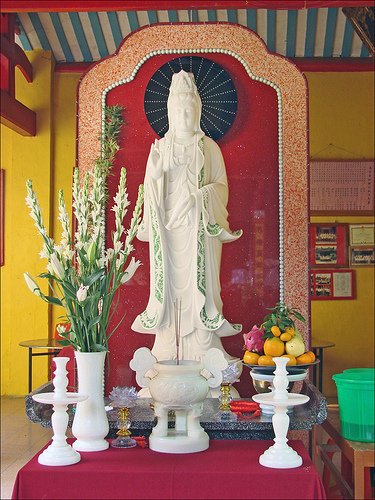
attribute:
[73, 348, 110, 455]
vase — white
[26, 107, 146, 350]
flowers — white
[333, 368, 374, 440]
tub — green, plastic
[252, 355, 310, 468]
candle holder — white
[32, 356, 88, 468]
candle holder — white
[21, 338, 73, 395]
table — glass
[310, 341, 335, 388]
table — glass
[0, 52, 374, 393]
wall — yellow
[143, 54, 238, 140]
medaillon — white, round, black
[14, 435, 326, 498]
cloth — red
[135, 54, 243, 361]
statue — white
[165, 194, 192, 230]
frisbee — white